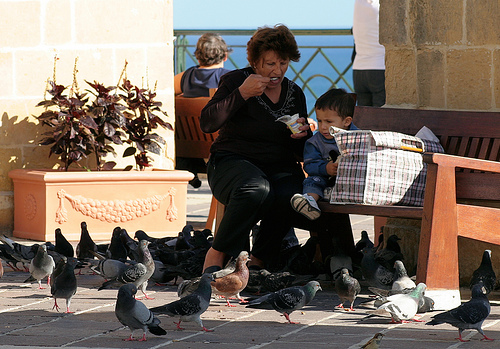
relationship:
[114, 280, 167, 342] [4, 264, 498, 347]
pigeon on ground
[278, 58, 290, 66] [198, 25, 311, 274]
eye of person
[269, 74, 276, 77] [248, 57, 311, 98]
spoon in mouth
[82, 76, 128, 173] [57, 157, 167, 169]
plants in planter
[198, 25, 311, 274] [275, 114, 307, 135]
person eating out of cup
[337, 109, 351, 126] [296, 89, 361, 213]
ear on boy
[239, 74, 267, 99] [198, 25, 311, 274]
hand on person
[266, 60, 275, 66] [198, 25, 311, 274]
eye on person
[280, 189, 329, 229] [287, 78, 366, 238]
feet on person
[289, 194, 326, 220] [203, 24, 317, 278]
feet on person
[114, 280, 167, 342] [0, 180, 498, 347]
pigeon on ground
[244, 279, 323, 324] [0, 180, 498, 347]
pigeon on ground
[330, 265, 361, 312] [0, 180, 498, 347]
pigeon on ground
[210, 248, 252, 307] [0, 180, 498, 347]
pigeon on ground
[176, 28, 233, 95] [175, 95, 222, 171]
man sitting on bench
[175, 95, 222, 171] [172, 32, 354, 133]
bench across from ocean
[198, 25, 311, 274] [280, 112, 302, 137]
person eating yogurt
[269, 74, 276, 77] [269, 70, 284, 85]
spoon inside mouth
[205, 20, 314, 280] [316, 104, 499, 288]
they on bench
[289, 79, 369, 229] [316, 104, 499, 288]
they on bench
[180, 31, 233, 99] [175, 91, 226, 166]
man on bench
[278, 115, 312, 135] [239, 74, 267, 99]
cup in hand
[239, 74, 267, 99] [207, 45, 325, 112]
hand on woman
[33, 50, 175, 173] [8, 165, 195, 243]
plants on stand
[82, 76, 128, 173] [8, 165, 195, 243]
plants on stand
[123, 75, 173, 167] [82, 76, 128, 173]
plants on plants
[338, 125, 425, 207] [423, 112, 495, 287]
bag on bench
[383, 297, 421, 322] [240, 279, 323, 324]
wing on pigeon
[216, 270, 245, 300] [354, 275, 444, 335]
wing on bird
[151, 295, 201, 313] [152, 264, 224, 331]
wing on bird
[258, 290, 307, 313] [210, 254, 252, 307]
wing on pigeon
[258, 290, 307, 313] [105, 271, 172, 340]
wing on bird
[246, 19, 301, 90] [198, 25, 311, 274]
head on person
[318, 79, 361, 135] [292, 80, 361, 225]
head on person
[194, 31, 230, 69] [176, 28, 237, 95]
head on person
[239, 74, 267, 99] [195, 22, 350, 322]
hand on person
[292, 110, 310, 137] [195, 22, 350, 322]
hand on person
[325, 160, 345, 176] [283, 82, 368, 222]
hand on person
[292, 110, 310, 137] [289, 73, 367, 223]
hand on person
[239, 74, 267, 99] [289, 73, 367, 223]
hand on person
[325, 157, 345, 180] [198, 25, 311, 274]
hand on person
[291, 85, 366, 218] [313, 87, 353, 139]
person has head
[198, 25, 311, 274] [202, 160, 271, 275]
person has leg